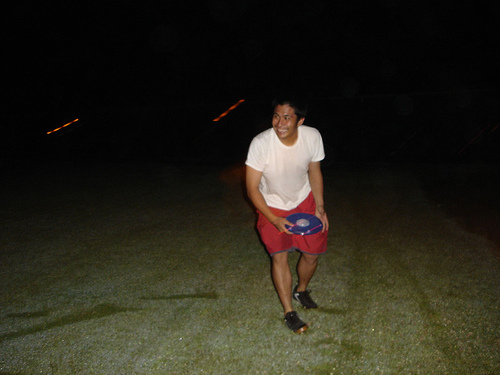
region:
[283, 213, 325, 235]
purple frisbee in the man's right hand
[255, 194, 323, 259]
the man is wearing red shorts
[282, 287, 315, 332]
black shoes on the man's feet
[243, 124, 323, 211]
the man is wearing a white shirt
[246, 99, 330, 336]
this man is playing frisbee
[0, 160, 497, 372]
green turf on the ground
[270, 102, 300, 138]
the man is smiling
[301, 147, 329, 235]
the man's left hand is slightly touching the frisbee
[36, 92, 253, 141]
stips of ambiguous lights in the background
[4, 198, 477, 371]
track lines seen on the grass ground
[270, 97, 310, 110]
black hair on man's head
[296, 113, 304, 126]
left ear on man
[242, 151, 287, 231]
the man's right arm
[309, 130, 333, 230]
the man's left arm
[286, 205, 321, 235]
blue frisbee in hand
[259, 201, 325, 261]
the man's red shorts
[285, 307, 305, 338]
shoe on man's right foot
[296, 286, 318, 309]
shoe on man's left foot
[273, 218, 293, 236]
the man's right hand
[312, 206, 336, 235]
the man's left hand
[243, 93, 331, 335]
man playing frisbee in dark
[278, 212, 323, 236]
the frisbee is blue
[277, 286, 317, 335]
the man is wearing shoes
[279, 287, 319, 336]
the shoes are athletic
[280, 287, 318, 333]
the shoes are black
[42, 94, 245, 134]
orange lights in background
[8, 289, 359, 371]
there are tracks in the dew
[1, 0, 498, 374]
the photo is a night action shot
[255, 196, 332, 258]
the man is wearing pink shorts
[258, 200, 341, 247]
a freesbie held by a man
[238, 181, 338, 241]
a freesbie in a man's hand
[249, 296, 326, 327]
a guy wearing black shoes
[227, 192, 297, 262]
a man wearing red shorts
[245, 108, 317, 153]
a smile placed on man's face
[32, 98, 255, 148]
stripe of lights shining on a field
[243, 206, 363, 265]
a white circle designed on a freezbie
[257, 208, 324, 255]
person wearing red shorts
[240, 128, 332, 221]
man wearing a white shirt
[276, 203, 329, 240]
man holding a frisbee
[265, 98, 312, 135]
man with black hair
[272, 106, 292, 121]
man with black hair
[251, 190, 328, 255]
man wearing red shorts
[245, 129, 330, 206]
man wearing a white shirt